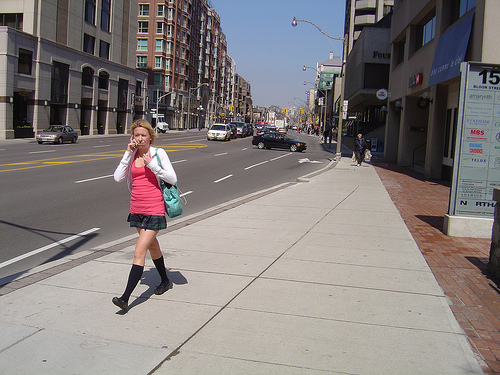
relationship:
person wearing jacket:
[347, 126, 369, 164] [352, 132, 369, 150]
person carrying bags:
[347, 126, 369, 164] [346, 146, 371, 164]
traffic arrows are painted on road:
[295, 149, 329, 167] [1, 125, 333, 286]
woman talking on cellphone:
[110, 111, 178, 313] [126, 137, 137, 153]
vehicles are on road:
[210, 112, 305, 152] [4, 112, 343, 300]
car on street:
[248, 126, 308, 157] [178, 140, 272, 191]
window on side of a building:
[136, 17, 150, 35] [133, 1, 167, 83]